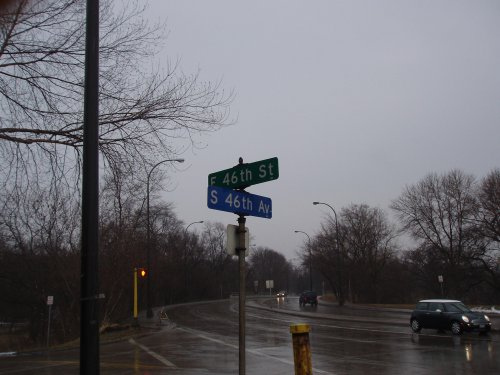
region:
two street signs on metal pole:
[200, 150, 287, 373]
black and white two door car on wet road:
[405, 291, 497, 346]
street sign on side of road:
[199, 148, 281, 374]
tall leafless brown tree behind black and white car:
[383, 163, 497, 302]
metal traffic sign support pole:
[228, 211, 255, 373]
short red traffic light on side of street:
[126, 260, 155, 330]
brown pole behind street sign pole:
[67, 1, 110, 373]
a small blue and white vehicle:
[408, 296, 492, 333]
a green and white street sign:
[208, 149, 285, 191]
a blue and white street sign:
[213, 188, 273, 215]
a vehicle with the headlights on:
[274, 286, 288, 301]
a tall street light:
[143, 150, 185, 319]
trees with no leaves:
[405, 172, 476, 248]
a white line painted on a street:
[130, 336, 169, 368]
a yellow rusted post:
[285, 320, 320, 373]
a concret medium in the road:
[260, 298, 339, 323]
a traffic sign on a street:
[263, 276, 278, 308]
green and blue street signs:
[202, 147, 281, 235]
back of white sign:
[223, 218, 255, 262]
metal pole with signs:
[230, 216, 252, 366]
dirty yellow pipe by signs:
[275, 315, 322, 370]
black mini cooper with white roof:
[411, 281, 493, 349]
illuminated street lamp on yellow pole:
[127, 255, 148, 318]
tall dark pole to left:
[65, 36, 113, 370]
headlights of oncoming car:
[270, 273, 289, 311]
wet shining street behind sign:
[212, 304, 386, 371]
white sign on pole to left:
[37, 275, 57, 334]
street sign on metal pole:
[203, 155, 277, 373]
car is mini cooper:
[408, 298, 492, 339]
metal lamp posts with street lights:
[144, 156, 343, 321]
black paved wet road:
[1, 289, 499, 374]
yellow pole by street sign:
[291, 325, 314, 373]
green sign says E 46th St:
[203, 155, 276, 188]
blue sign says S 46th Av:
[205, 185, 272, 219]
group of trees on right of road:
[298, 163, 498, 306]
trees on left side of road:
[1, 0, 313, 350]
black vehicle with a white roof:
[406, 298, 496, 340]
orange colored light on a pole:
[139, 269, 145, 279]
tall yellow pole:
[130, 265, 142, 332]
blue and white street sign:
[207, 187, 278, 219]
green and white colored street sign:
[203, 155, 283, 191]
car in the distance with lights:
[274, 287, 289, 301]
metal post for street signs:
[235, 212, 251, 373]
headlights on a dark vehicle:
[460, 313, 492, 328]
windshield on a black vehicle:
[445, 300, 467, 313]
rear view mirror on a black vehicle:
[436, 305, 445, 317]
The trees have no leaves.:
[398, 150, 498, 285]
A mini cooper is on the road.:
[396, 289, 491, 347]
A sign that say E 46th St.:
[206, 153, 285, 188]